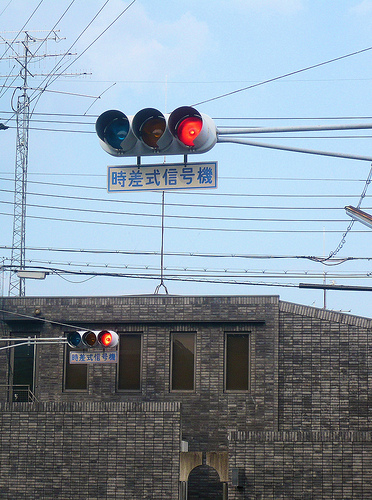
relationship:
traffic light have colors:
[77, 106, 239, 170] [104, 117, 196, 135]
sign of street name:
[93, 160, 247, 200] [204, 167, 211, 188]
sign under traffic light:
[93, 160, 247, 200] [77, 106, 239, 170]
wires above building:
[4, 21, 151, 91] [295, 333, 352, 373]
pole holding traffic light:
[213, 125, 369, 146] [77, 106, 239, 170]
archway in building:
[165, 432, 248, 495] [295, 333, 352, 373]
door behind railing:
[13, 335, 45, 406] [3, 382, 41, 405]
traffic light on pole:
[77, 106, 239, 170] [213, 125, 369, 146]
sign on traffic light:
[93, 160, 247, 200] [77, 106, 239, 170]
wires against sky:
[4, 21, 151, 91] [292, 18, 308, 19]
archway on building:
[165, 432, 248, 495] [295, 333, 352, 373]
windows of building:
[51, 374, 276, 410] [295, 333, 352, 373]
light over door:
[15, 301, 70, 326] [13, 335, 45, 406]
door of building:
[13, 335, 45, 406] [295, 333, 352, 373]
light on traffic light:
[15, 301, 70, 326] [77, 106, 239, 170]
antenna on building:
[6, 28, 51, 290] [295, 333, 352, 373]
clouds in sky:
[139, 26, 229, 58] [292, 18, 308, 19]